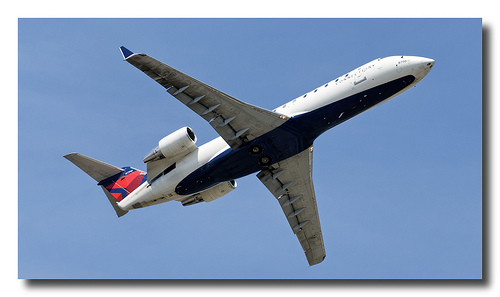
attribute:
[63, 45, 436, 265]
airplane — white, in the air, passenger, commercial, present, in flight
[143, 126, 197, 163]
engine — right side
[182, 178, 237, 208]
engine — left side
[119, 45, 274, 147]
wing — bent, white, right side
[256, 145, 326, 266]
wing — bent, white, left side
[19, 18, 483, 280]
sky — blue, clear, bright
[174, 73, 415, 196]
bottom — painted blue, blue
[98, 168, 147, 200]
design — red, blue, red white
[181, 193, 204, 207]
ending — silver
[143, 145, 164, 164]
tip — silver